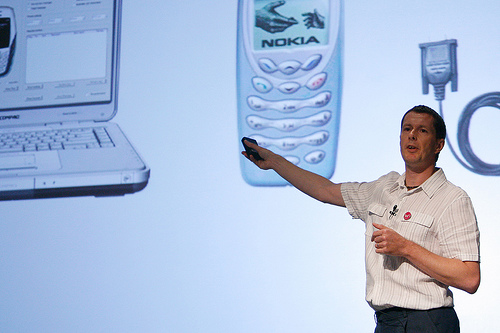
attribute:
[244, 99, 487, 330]
man — standing, Caucasian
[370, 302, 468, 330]
pants — black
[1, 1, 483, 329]
background — white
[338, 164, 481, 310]
shirt — white, striped, short sleeved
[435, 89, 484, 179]
cable — coiled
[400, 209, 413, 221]
patch — red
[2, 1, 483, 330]
image — large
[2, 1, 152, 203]
laptop — light colored, open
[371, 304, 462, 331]
pants — black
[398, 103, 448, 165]
hair — short, dark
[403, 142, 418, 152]
mouth — partially open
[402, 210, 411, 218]
button — red, round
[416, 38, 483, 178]
computer cable — gray, wound up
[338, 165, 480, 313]
top — light colored, striped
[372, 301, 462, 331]
dress pants — black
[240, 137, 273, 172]
hand — outstretched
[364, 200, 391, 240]
shirt pocket — light colored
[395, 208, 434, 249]
shirt pocket — light colored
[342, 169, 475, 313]
shirt — white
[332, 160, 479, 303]
shirt — white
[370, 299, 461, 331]
pants — blue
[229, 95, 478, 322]
man — pointing, giving presentation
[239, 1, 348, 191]
image — large, nokia phone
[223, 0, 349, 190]
graphic — large, nokia cell phone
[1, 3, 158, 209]
graphic — silver laptop, large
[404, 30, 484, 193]
graphic — large, electric cord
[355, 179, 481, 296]
forearm — caucasian male's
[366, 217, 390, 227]
thumbs — up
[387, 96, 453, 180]
head — caucasian male's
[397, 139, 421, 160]
mouth — open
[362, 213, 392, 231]
thumb — up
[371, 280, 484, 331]
pants — male's, caucasian male's, upper half